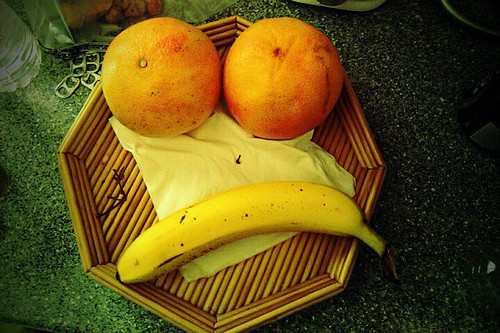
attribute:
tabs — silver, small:
[37, 40, 109, 101]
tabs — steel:
[42, 37, 110, 110]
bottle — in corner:
[2, 2, 43, 101]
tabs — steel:
[54, 50, 109, 102]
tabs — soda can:
[47, 43, 108, 115]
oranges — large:
[94, 15, 346, 142]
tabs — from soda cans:
[53, 46, 108, 98]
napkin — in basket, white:
[74, 82, 386, 290]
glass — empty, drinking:
[0, 50, 80, 67]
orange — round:
[222, 14, 347, 138]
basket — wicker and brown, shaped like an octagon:
[58, 15, 393, 332]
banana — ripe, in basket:
[99, 202, 394, 258]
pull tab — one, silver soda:
[53, 75, 76, 97]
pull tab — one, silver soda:
[70, 55, 86, 76]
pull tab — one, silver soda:
[85, 50, 99, 71]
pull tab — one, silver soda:
[81, 70, 98, 87]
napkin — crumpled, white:
[101, 92, 357, 268]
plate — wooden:
[161, 284, 318, 328]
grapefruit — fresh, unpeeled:
[223, 15, 343, 143]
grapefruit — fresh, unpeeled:
[97, 13, 222, 138]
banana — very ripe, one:
[111, 177, 386, 286]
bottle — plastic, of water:
[0, 0, 45, 95]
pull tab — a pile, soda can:
[53, 71, 78, 99]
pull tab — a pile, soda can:
[67, 52, 87, 77]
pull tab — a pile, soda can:
[84, 48, 100, 74]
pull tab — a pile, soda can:
[77, 68, 98, 88]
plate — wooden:
[55, 13, 384, 328]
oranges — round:
[233, 55, 325, 127]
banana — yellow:
[110, 158, 405, 315]